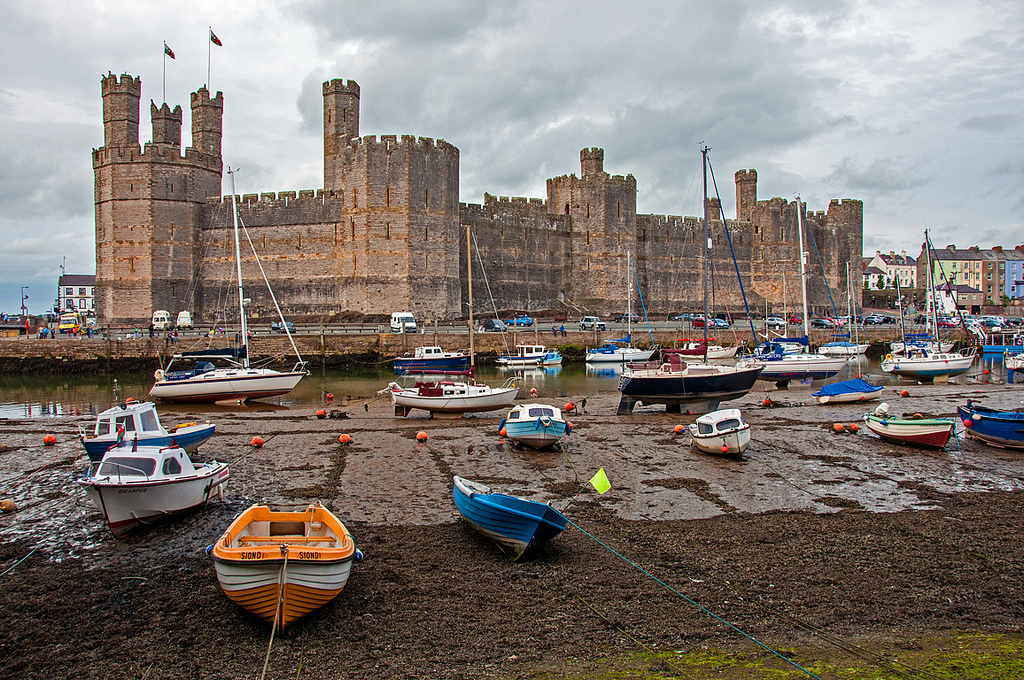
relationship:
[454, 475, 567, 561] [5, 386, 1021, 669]
blue boat on ground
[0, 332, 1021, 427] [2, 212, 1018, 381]
water on background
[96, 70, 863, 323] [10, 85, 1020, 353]
building on background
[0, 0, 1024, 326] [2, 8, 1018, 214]
background in sky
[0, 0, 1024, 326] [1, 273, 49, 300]
background in sky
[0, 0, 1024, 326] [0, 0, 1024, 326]
background in background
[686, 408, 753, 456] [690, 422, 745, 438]
boat with stripe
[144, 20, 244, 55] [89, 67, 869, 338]
two flags at top of building